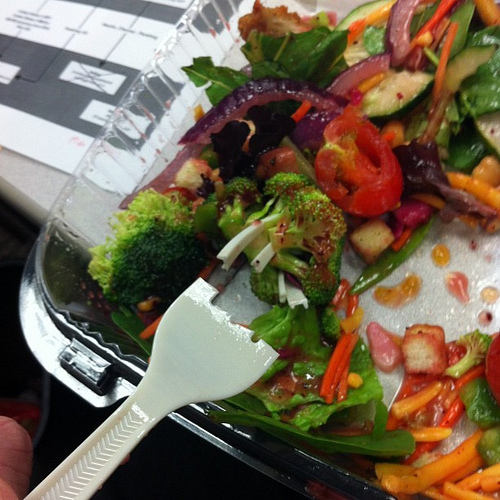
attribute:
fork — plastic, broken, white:
[55, 298, 283, 482]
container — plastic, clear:
[42, 57, 486, 490]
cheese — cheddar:
[387, 391, 434, 451]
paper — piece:
[15, 23, 182, 154]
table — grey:
[17, 156, 118, 244]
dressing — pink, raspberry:
[249, 73, 433, 260]